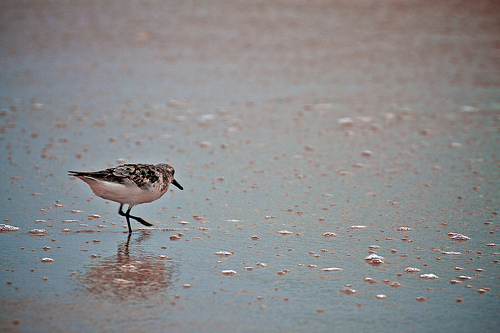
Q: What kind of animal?
A: Bird.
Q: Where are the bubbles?
A: Surface of water.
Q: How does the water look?
A: Calm and brown.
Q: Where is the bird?
A: On ground.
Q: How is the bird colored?
A: Dark and light.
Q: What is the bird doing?
A: Walking.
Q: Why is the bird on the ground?
A: Not flying.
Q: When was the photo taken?
A: Daylight.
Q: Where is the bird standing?
A: On beach.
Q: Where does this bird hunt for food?
A: The beach.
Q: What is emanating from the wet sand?
A: Bubbles.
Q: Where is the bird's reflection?
A: Underneath the bird.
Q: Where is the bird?
A: On the ground.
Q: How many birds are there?
A: One.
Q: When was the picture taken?
A: Daytime.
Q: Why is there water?
A: The bird is on a beach.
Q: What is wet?
A: The water.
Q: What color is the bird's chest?
A: White.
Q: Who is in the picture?
A: Nobody.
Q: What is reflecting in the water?
A: The bird.